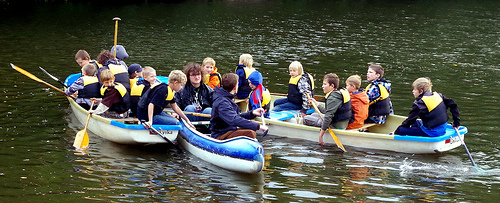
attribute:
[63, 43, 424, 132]
kids — playing, rowing, canoeing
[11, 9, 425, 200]
water — calm, clear, large body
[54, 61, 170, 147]
canoe — white, blue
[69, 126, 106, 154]
oar — top, red, yellow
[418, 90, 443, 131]
vest — yellow, blue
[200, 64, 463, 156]
boat — white, blue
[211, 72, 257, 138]
person — sitting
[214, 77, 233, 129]
jacket — blue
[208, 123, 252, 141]
pants — brown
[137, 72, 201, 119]
boy — young, blonde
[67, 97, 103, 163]
paddle — yellow, long, wooden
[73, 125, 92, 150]
tip — yellow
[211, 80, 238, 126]
rain coat — blue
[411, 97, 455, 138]
life vest — yellow, blue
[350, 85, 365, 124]
coat — orange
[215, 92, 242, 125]
coat — dark blue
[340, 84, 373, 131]
jacket — orange